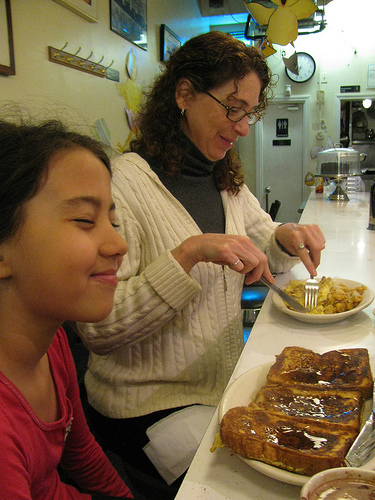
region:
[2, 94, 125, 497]
a little girl smiling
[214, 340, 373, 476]
three pieces of toast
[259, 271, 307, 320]
thats a silver knife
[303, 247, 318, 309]
thats a silver fork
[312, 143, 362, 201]
this is a cake pan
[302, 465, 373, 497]
thats a cup of hot cocoa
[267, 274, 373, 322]
this is a white bowl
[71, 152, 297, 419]
thats her white sweater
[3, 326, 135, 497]
this is her red shirt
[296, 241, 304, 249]
this is her ring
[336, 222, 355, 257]
Part of the table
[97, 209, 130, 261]
The nose of the girl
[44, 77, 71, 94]
Part of the wall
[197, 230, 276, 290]
The right hand of the woman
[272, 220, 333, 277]
The left hand of the woman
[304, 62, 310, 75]
Part of the clock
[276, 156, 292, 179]
Part of the door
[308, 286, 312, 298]
Part of the fork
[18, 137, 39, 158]
Part of the hair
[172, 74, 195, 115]
The right ear of the woman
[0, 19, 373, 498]
a mother and daughter are sitting at the counter to eat breakfast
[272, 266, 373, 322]
a bowl filled with eggs and hashbrowns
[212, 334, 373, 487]
a plate with french toast covered in syrup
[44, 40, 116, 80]
a shelf with hooks is on the wall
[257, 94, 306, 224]
the restroom is marked for both males and females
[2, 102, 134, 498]
the girl is sitting with her eyes closed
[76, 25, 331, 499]
the woman is cutting her food with a knife and fork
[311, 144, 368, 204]
a chocolate cake displayed on a cake stand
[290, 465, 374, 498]
a cup of hot chocolate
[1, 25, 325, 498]
the woman and the girl have brown hair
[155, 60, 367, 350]
woman is cutting her food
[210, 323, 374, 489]
three French toast on plate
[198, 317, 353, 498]
three French toasts on plate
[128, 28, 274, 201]
woman has curly brown hair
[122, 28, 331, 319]
woman holds a knife and fork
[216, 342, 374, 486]
three pieces of french toast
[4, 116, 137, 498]
young girl wears a pink shirt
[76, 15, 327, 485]
woman has a paper napkin on her lap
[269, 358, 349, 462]
syrup laying on some toast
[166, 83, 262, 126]
a pair of brown framed glasses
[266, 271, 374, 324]
a small white bowl full of food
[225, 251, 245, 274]
silver ring on a finger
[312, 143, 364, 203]
cake on a silver stand with a glass dome